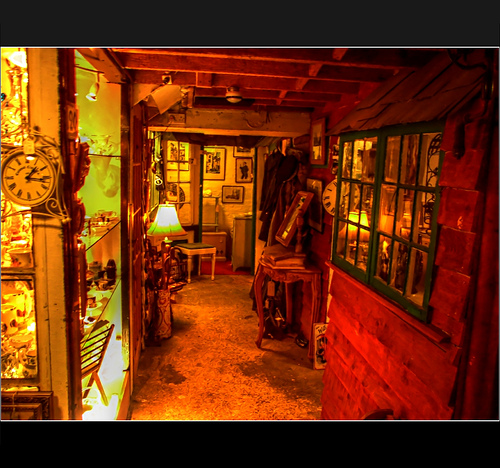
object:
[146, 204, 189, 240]
lamp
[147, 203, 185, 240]
lamp shade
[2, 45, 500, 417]
room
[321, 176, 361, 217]
round clock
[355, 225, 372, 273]
pane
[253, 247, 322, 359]
table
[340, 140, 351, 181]
pane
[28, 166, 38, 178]
hands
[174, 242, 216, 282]
stool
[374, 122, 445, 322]
green frame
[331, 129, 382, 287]
green frame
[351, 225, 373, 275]
window pane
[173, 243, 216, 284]
chair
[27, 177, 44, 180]
hand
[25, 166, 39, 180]
hand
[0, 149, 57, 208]
clock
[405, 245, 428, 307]
pane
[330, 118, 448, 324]
window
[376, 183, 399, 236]
panes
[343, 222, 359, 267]
pane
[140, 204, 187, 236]
shade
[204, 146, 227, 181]
picture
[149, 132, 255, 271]
wall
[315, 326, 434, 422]
wall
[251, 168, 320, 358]
stand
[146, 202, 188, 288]
light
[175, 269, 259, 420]
hallway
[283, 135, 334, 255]
wall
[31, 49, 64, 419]
frame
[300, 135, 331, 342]
wall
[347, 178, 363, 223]
pane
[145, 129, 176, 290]
corner